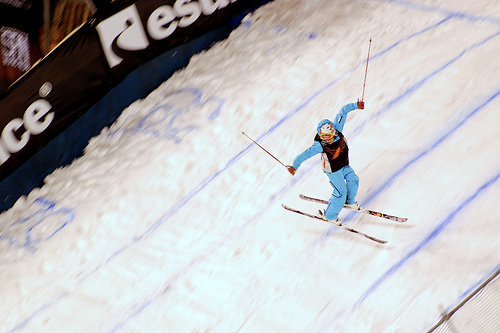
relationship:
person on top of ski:
[287, 100, 367, 223] [280, 201, 390, 254]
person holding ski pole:
[287, 100, 367, 223] [360, 31, 374, 98]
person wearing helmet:
[287, 100, 367, 223] [318, 124, 338, 141]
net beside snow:
[2, 16, 272, 216] [2, 0, 499, 331]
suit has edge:
[314, 131, 351, 173] [320, 148, 333, 175]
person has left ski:
[287, 100, 367, 223] [294, 189, 410, 231]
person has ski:
[287, 100, 367, 223] [280, 201, 390, 254]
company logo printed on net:
[94, 7, 151, 70] [2, 16, 272, 216]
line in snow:
[354, 173, 500, 307] [2, 0, 499, 331]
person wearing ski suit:
[287, 100, 367, 223] [292, 101, 361, 219]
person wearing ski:
[287, 100, 367, 223] [280, 201, 390, 254]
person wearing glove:
[287, 100, 367, 223] [284, 163, 299, 179]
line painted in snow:
[354, 173, 500, 307] [2, 0, 499, 331]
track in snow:
[254, 3, 299, 38] [2, 0, 499, 331]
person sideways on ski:
[287, 100, 367, 223] [280, 201, 390, 254]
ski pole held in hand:
[360, 31, 374, 98] [356, 96, 368, 114]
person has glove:
[287, 100, 367, 223] [284, 163, 299, 179]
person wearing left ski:
[287, 100, 367, 223] [294, 189, 410, 231]